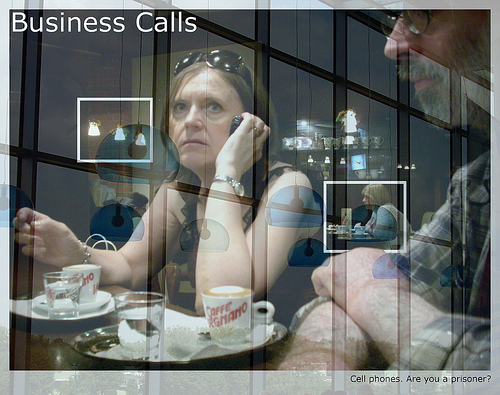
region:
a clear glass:
[112, 287, 168, 359]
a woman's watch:
[205, 168, 250, 199]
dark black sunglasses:
[160, 47, 260, 84]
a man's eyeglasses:
[375, 10, 433, 33]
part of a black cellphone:
[227, 112, 242, 137]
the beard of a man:
[400, 28, 491, 135]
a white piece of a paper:
[97, 303, 278, 363]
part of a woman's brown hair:
[216, 65, 279, 190]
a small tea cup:
[199, 284, 279, 345]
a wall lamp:
[305, 150, 317, 164]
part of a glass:
[138, 178, 166, 205]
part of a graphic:
[368, 365, 409, 388]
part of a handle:
[253, 298, 277, 325]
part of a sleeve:
[404, 329, 435, 372]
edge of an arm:
[235, 246, 263, 286]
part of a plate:
[222, 345, 234, 354]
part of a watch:
[236, 184, 247, 201]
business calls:
[9, 3, 280, 104]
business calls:
[2, 7, 184, 82]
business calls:
[14, 11, 226, 36]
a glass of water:
[71, 206, 251, 355]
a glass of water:
[80, 251, 204, 377]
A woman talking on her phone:
[35, 64, 338, 312]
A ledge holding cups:
[268, 130, 399, 192]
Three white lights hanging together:
[78, 108, 154, 148]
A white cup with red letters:
[198, 279, 290, 351]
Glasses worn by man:
[364, 9, 455, 66]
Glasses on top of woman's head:
[158, 48, 259, 103]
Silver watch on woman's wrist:
[214, 166, 250, 203]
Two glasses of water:
[44, 268, 197, 375]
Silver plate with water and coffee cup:
[60, 299, 293, 375]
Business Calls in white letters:
[10, 5, 207, 49]